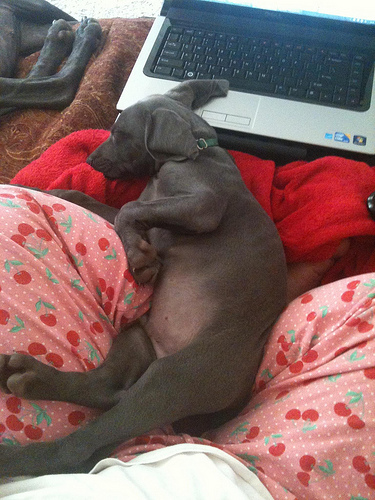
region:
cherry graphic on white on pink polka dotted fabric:
[335, 386, 368, 436]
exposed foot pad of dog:
[0, 351, 40, 397]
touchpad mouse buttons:
[201, 105, 259, 125]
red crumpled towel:
[272, 172, 358, 228]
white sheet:
[112, 475, 224, 499]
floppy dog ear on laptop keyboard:
[162, 71, 231, 111]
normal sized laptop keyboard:
[169, 24, 373, 103]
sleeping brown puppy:
[6, 77, 291, 459]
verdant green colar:
[195, 133, 218, 151]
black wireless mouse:
[356, 188, 373, 226]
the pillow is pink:
[261, 366, 300, 495]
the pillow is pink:
[271, 390, 313, 494]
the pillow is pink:
[295, 390, 312, 479]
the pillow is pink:
[289, 441, 306, 496]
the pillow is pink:
[289, 368, 327, 460]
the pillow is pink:
[284, 410, 327, 498]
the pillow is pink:
[343, 332, 369, 380]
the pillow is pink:
[289, 339, 342, 479]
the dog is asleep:
[180, 205, 255, 461]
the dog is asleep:
[149, 207, 210, 398]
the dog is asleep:
[125, 243, 195, 405]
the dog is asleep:
[197, 281, 222, 386]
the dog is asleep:
[172, 290, 206, 394]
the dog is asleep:
[174, 271, 242, 409]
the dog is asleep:
[180, 265, 300, 487]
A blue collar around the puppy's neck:
[189, 133, 221, 157]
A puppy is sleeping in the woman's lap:
[3, 77, 291, 473]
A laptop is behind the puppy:
[116, 0, 372, 156]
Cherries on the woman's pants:
[282, 404, 320, 436]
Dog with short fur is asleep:
[5, 76, 288, 472]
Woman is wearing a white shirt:
[5, 475, 277, 498]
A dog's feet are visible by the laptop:
[19, 14, 101, 110]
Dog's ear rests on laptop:
[162, 73, 234, 115]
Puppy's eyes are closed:
[111, 124, 132, 144]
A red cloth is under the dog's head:
[11, 124, 369, 252]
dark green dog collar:
[177, 130, 235, 167]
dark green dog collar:
[181, 133, 220, 152]